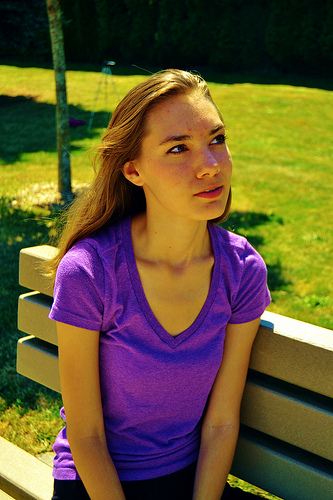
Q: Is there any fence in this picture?
A: No, there are no fences.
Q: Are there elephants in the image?
A: No, there are no elephants.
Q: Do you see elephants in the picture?
A: No, there are no elephants.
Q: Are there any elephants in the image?
A: No, there are no elephants.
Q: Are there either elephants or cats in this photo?
A: No, there are no elephants or cats.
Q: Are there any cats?
A: No, there are no cats.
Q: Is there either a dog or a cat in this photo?
A: No, there are no cats or dogs.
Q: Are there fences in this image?
A: No, there are no fences.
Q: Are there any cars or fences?
A: No, there are no fences or cars.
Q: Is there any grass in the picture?
A: Yes, there is grass.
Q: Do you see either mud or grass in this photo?
A: Yes, there is grass.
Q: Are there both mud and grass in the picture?
A: No, there is grass but no mud.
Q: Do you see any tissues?
A: No, there are no tissues.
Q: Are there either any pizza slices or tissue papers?
A: No, there are no tissue papers or pizza slices.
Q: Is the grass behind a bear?
A: No, the grass is behind a bench.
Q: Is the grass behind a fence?
A: No, the grass is behind a girl.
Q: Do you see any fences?
A: No, there are no fences.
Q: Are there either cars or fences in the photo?
A: No, there are no fences or cars.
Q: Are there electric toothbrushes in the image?
A: No, there are no electric toothbrushes.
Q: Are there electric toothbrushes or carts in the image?
A: No, there are no electric toothbrushes or carts.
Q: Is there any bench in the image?
A: Yes, there is a bench.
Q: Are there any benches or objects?
A: Yes, there is a bench.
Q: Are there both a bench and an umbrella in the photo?
A: No, there is a bench but no umbrellas.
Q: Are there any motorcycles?
A: No, there are no motorcycles.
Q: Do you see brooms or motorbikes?
A: No, there are no motorbikes or brooms.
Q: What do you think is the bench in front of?
A: The bench is in front of the grass.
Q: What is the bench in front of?
A: The bench is in front of the grass.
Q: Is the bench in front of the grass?
A: Yes, the bench is in front of the grass.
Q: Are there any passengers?
A: No, there are no passengers.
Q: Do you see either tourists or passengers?
A: No, there are no passengers or tourists.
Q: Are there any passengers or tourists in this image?
A: No, there are no passengers or tourists.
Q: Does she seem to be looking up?
A: Yes, the girl is looking up.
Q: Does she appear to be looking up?
A: Yes, the girl is looking up.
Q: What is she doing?
A: The girl is looking up.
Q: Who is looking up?
A: The girl is looking up.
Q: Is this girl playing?
A: No, the girl is looking up.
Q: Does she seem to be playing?
A: No, the girl is looking up.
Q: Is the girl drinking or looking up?
A: The girl is looking up.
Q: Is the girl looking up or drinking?
A: The girl is looking up.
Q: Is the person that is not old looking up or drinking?
A: The girl is looking up.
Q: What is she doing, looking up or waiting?
A: The girl is looking up.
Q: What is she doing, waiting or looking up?
A: The girl is looking up.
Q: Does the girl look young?
A: Yes, the girl is young.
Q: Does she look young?
A: Yes, the girl is young.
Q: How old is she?
A: The girl is young.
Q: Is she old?
A: No, the girl is young.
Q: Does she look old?
A: No, the girl is young.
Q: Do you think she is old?
A: No, the girl is young.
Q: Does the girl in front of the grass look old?
A: No, the girl is young.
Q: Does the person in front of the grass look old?
A: No, the girl is young.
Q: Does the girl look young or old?
A: The girl is young.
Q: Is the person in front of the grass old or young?
A: The girl is young.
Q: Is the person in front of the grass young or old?
A: The girl is young.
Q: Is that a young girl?
A: Yes, that is a young girl.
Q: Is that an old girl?
A: No, that is a young girl.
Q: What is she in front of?
A: The girl is in front of the grass.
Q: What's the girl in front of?
A: The girl is in front of the grass.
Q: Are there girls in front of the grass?
A: Yes, there is a girl in front of the grass.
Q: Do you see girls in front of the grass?
A: Yes, there is a girl in front of the grass.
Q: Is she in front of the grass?
A: Yes, the girl is in front of the grass.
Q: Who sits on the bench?
A: The girl sits on the bench.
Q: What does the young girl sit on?
A: The girl sits on the bench.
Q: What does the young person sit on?
A: The girl sits on the bench.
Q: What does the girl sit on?
A: The girl sits on the bench.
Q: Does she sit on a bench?
A: Yes, the girl sits on a bench.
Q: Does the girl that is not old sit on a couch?
A: No, the girl sits on a bench.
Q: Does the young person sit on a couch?
A: No, the girl sits on a bench.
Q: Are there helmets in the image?
A: No, there are no helmets.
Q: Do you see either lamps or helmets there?
A: No, there are no helmets or lamps.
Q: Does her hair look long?
A: Yes, the hair is long.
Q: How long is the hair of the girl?
A: The hair is long.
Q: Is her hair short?
A: No, the hair is long.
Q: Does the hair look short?
A: No, the hair is long.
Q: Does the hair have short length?
A: No, the hair is long.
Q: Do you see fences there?
A: No, there are no fences.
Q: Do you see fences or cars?
A: No, there are no fences or cars.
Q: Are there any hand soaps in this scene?
A: No, there are no hand soaps.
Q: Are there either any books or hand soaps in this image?
A: No, there are no hand soaps or books.